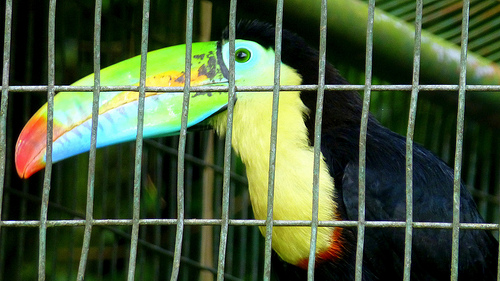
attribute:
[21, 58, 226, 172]
beak — red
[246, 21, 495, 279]
feathers — black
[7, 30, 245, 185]
beak — colorful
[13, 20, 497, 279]
bird — large, toucan, Amazon rain forest, black, yellow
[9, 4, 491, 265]
cage — silver, metal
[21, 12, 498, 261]
bird — red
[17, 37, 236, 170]
beak — green 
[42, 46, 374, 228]
feathers — yellow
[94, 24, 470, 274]
cage — gray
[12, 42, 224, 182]
beak — green, blue, red, long, yellow, large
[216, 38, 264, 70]
eye — green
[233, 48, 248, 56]
eyes — green, black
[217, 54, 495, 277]
feathers — red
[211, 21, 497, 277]
body — Toucans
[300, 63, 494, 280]
body — black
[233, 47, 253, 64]
eye — round